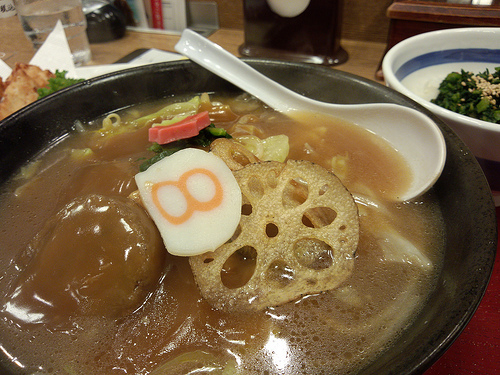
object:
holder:
[240, 0, 344, 63]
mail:
[149, 0, 163, 29]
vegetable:
[429, 97, 499, 123]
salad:
[410, 32, 500, 129]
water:
[19, 3, 93, 66]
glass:
[23, 2, 91, 66]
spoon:
[175, 28, 446, 205]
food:
[0, 24, 500, 372]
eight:
[150, 168, 221, 224]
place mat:
[429, 290, 499, 375]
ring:
[400, 23, 499, 39]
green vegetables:
[430, 67, 498, 121]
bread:
[0, 63, 56, 126]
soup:
[313, 202, 446, 373]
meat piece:
[28, 197, 161, 319]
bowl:
[2, 59, 498, 375]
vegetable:
[186, 139, 349, 314]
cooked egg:
[134, 147, 241, 256]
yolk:
[158, 185, 186, 217]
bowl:
[381, 27, 500, 161]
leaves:
[41, 66, 83, 93]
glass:
[84, 4, 127, 40]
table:
[2, 2, 494, 374]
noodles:
[326, 269, 421, 350]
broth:
[254, 110, 412, 199]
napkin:
[135, 48, 191, 65]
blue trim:
[449, 48, 498, 62]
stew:
[3, 306, 414, 375]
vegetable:
[431, 70, 468, 117]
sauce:
[456, 70, 485, 101]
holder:
[121, 1, 219, 37]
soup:
[0, 119, 134, 375]